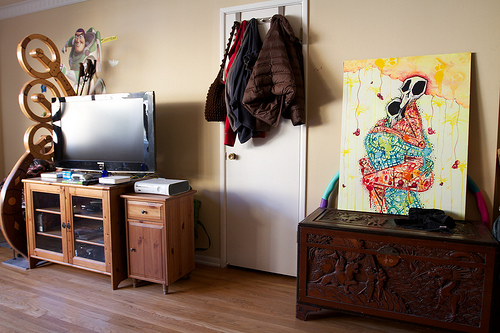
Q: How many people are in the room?
A: 0.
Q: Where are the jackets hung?
A: On the door.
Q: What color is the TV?
A: Black.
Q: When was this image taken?
A: Daytime.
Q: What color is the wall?
A: Tan.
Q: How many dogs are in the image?
A: 0.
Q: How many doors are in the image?
A: 1.